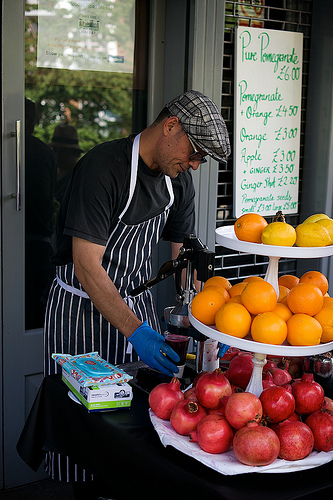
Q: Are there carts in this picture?
A: No, there are no carts.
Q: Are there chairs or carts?
A: No, there are no carts or chairs.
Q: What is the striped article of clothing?
A: The clothing item is an apron.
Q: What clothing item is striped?
A: The clothing item is an apron.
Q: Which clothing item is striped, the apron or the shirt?
A: The apron is striped.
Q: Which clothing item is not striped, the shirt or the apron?
A: The shirt is not striped.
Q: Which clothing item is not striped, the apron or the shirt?
A: The shirt is not striped.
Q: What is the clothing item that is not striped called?
A: The clothing item is a shirt.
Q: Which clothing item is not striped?
A: The clothing item is a shirt.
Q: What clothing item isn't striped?
A: The clothing item is a shirt.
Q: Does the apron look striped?
A: Yes, the apron is striped.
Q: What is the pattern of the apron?
A: The apron is striped.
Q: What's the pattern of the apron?
A: The apron is striped.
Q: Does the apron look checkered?
A: No, the apron is striped.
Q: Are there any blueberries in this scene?
A: No, there are no blueberries.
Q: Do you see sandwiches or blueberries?
A: No, there are no blueberries or sandwiches.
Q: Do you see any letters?
A: Yes, there are letters.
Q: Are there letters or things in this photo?
A: Yes, there are letters.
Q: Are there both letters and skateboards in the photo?
A: No, there are letters but no skateboards.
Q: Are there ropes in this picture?
A: No, there are no ropes.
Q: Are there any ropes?
A: No, there are no ropes.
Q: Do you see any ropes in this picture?
A: No, there are no ropes.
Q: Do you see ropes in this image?
A: No, there are no ropes.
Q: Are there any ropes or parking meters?
A: No, there are no ropes or parking meters.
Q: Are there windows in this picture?
A: Yes, there is a window.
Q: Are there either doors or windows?
A: Yes, there is a window.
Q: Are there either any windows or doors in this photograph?
A: Yes, there is a window.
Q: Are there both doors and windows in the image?
A: Yes, there are both a window and a door.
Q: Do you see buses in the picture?
A: No, there are no buses.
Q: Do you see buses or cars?
A: No, there are no buses or cars.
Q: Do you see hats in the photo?
A: Yes, there is a hat.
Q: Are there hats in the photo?
A: Yes, there is a hat.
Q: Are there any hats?
A: Yes, there is a hat.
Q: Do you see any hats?
A: Yes, there is a hat.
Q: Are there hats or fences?
A: Yes, there is a hat.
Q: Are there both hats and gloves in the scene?
A: Yes, there are both a hat and gloves.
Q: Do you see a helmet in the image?
A: No, there are no helmets.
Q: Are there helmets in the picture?
A: No, there are no helmets.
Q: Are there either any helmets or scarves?
A: No, there are no helmets or scarves.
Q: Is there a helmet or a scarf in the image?
A: No, there are no helmets or scarves.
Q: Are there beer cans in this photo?
A: No, there are no beer cans.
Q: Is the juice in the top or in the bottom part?
A: The juice is in the bottom of the image.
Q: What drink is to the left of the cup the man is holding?
A: The drink is juice.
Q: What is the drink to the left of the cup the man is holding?
A: The drink is juice.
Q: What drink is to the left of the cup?
A: The drink is juice.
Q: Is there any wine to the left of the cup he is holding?
A: No, there is juice to the left of the cup.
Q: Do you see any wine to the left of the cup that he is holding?
A: No, there is juice to the left of the cup.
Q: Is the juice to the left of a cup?
A: Yes, the juice is to the left of a cup.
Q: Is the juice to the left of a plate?
A: No, the juice is to the left of a cup.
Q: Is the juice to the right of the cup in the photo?
A: No, the juice is to the left of the cup.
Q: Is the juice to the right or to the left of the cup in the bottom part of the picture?
A: The juice is to the left of the cup.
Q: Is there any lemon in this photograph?
A: Yes, there is a lemon.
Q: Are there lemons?
A: Yes, there is a lemon.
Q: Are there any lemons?
A: Yes, there is a lemon.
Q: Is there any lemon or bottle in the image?
A: Yes, there is a lemon.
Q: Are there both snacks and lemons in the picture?
A: No, there is a lemon but no snacks.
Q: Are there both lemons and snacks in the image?
A: No, there is a lemon but no snacks.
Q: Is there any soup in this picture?
A: No, there is no soup.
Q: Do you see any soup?
A: No, there is no soup.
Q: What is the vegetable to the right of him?
A: The vegetable is a lemon.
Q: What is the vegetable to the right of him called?
A: The vegetable is a lemon.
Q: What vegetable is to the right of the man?
A: The vegetable is a lemon.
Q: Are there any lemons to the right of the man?
A: Yes, there is a lemon to the right of the man.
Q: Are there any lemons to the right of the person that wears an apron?
A: Yes, there is a lemon to the right of the man.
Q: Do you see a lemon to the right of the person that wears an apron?
A: Yes, there is a lemon to the right of the man.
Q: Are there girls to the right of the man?
A: No, there is a lemon to the right of the man.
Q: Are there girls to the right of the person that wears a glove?
A: No, there is a lemon to the right of the man.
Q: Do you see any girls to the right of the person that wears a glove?
A: No, there is a lemon to the right of the man.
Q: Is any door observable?
A: Yes, there is a door.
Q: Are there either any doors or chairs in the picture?
A: Yes, there is a door.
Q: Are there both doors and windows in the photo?
A: Yes, there are both a door and a window.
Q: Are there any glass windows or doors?
A: Yes, there is a glass door.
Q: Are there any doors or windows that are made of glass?
A: Yes, the door is made of glass.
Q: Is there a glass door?
A: Yes, there is a door that is made of glass.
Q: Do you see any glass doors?
A: Yes, there is a door that is made of glass.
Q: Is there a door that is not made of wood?
A: Yes, there is a door that is made of glass.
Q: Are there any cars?
A: No, there are no cars.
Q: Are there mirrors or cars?
A: No, there are no cars or mirrors.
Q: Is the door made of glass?
A: Yes, the door is made of glass.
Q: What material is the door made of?
A: The door is made of glass.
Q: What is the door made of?
A: The door is made of glass.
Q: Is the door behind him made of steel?
A: No, the door is made of glass.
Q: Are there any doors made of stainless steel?
A: No, there is a door but it is made of glass.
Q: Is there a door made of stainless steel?
A: No, there is a door but it is made of glass.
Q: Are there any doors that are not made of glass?
A: No, there is a door but it is made of glass.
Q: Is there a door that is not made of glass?
A: No, there is a door but it is made of glass.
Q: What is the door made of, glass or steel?
A: The door is made of glass.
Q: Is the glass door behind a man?
A: Yes, the door is behind a man.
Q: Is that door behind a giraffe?
A: No, the door is behind a man.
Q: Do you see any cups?
A: Yes, there is a cup.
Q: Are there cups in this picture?
A: Yes, there is a cup.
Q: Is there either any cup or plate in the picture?
A: Yes, there is a cup.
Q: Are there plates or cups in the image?
A: Yes, there is a cup.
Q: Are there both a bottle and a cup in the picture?
A: No, there is a cup but no bottles.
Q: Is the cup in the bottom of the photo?
A: Yes, the cup is in the bottom of the image.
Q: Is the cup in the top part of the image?
A: No, the cup is in the bottom of the image.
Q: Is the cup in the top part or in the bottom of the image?
A: The cup is in the bottom of the image.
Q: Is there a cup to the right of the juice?
A: Yes, there is a cup to the right of the juice.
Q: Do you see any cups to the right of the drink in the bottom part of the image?
A: Yes, there is a cup to the right of the juice.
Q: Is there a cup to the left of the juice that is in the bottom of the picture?
A: No, the cup is to the right of the juice.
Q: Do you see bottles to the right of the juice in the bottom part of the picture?
A: No, there is a cup to the right of the juice.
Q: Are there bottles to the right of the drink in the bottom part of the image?
A: No, there is a cup to the right of the juice.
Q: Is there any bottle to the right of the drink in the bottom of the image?
A: No, there is a cup to the right of the juice.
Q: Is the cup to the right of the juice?
A: Yes, the cup is to the right of the juice.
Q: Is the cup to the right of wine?
A: No, the cup is to the right of the juice.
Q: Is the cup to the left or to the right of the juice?
A: The cup is to the right of the juice.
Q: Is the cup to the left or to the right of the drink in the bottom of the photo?
A: The cup is to the right of the juice.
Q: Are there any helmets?
A: No, there are no helmets.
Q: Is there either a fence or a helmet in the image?
A: No, there are no helmets or fences.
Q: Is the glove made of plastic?
A: Yes, the glove is made of plastic.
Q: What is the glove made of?
A: The glove is made of plastic.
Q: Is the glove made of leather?
A: No, the glove is made of plastic.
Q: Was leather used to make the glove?
A: No, the glove is made of plastic.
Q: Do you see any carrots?
A: No, there are no carrots.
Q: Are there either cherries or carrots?
A: No, there are no carrots or cherries.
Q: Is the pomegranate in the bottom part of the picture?
A: Yes, the pomegranate is in the bottom of the image.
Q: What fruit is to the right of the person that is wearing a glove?
A: The fruit is a pomegranate.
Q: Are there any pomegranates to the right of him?
A: Yes, there is a pomegranate to the right of the man.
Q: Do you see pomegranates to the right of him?
A: Yes, there is a pomegranate to the right of the man.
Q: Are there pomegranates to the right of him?
A: Yes, there is a pomegranate to the right of the man.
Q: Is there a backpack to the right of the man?
A: No, there is a pomegranate to the right of the man.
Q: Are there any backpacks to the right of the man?
A: No, there is a pomegranate to the right of the man.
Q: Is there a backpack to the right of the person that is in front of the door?
A: No, there is a pomegranate to the right of the man.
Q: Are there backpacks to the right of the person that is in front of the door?
A: No, there is a pomegranate to the right of the man.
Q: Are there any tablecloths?
A: Yes, there is a tablecloth.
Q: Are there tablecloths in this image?
A: Yes, there is a tablecloth.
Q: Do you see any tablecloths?
A: Yes, there is a tablecloth.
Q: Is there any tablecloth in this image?
A: Yes, there is a tablecloth.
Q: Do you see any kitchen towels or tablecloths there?
A: Yes, there is a tablecloth.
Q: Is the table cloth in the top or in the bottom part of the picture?
A: The table cloth is in the bottom of the image.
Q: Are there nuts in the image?
A: No, there are no nuts.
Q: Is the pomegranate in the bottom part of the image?
A: Yes, the pomegranate is in the bottom of the image.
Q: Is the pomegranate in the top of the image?
A: No, the pomegranate is in the bottom of the image.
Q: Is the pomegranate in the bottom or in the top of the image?
A: The pomegranate is in the bottom of the image.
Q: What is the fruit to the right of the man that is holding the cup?
A: The fruit is a pomegranate.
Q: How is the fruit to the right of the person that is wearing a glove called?
A: The fruit is a pomegranate.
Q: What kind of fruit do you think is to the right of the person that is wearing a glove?
A: The fruit is a pomegranate.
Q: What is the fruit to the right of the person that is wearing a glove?
A: The fruit is a pomegranate.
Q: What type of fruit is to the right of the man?
A: The fruit is a pomegranate.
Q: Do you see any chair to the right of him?
A: No, there is a pomegranate to the right of the man.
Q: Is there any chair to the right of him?
A: No, there is a pomegranate to the right of the man.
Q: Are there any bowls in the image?
A: No, there are no bowls.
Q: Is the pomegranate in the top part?
A: No, the pomegranate is in the bottom of the image.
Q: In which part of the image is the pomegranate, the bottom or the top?
A: The pomegranate is in the bottom of the image.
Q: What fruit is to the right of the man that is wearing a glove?
A: The fruit is a pomegranate.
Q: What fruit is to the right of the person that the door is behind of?
A: The fruit is a pomegranate.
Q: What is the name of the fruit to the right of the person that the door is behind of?
A: The fruit is a pomegranate.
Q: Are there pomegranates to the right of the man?
A: Yes, there is a pomegranate to the right of the man.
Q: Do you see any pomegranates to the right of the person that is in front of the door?
A: Yes, there is a pomegranate to the right of the man.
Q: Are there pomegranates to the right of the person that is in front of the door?
A: Yes, there is a pomegranate to the right of the man.